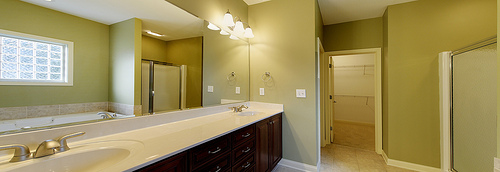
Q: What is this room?
A: A bathroom.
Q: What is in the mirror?
A: A reflection of the window.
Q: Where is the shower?
A: To the right.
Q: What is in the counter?
A: 2 sinks.